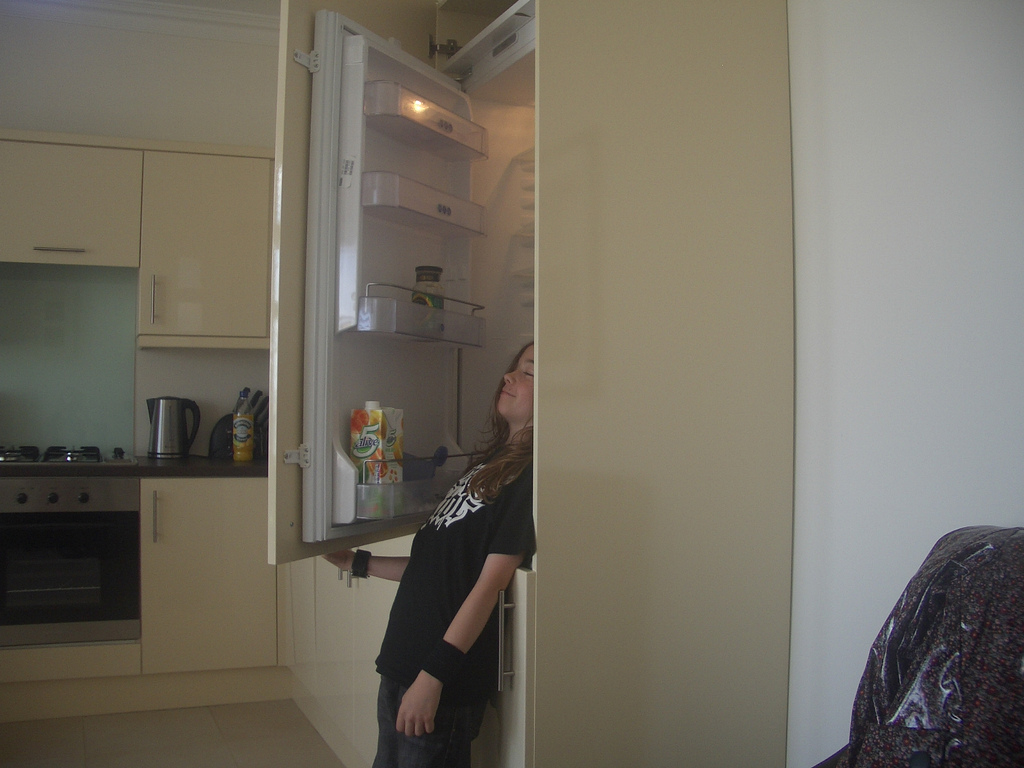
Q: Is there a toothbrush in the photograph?
A: No, there are no toothbrushes.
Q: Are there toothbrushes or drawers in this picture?
A: No, there are no toothbrushes or drawers.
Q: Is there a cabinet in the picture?
A: Yes, there is a cabinet.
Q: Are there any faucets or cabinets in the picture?
A: Yes, there is a cabinet.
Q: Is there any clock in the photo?
A: No, there are no clocks.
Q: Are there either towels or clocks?
A: No, there are no clocks or towels.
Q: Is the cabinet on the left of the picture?
A: Yes, the cabinet is on the left of the image.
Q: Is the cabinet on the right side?
A: No, the cabinet is on the left of the image.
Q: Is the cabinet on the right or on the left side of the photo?
A: The cabinet is on the left of the image.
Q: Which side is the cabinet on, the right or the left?
A: The cabinet is on the left of the image.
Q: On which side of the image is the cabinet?
A: The cabinet is on the left of the image.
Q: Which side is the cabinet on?
A: The cabinet is on the left of the image.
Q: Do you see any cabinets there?
A: Yes, there is a cabinet.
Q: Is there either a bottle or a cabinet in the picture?
A: Yes, there is a cabinet.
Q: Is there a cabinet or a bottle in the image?
A: Yes, there is a cabinet.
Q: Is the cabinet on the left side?
A: Yes, the cabinet is on the left of the image.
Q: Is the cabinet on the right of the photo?
A: No, the cabinet is on the left of the image.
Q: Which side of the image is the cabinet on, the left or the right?
A: The cabinet is on the left of the image.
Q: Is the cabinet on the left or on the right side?
A: The cabinet is on the left of the image.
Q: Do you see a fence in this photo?
A: No, there are no fences.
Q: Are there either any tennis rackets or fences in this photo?
A: No, there are no fences or tennis rackets.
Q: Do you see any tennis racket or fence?
A: No, there are no fences or rackets.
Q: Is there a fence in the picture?
A: No, there are no fences.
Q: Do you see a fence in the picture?
A: No, there are no fences.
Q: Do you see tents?
A: No, there are no tents.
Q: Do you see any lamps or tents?
A: No, there are no tents or lamps.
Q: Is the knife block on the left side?
A: Yes, the knife block is on the left of the image.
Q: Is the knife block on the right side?
A: No, the knife block is on the left of the image.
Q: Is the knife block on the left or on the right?
A: The knife block is on the left of the image.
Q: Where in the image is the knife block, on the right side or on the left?
A: The knife block is on the left of the image.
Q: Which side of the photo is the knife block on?
A: The knife block is on the left of the image.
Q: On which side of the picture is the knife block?
A: The knife block is on the left of the image.